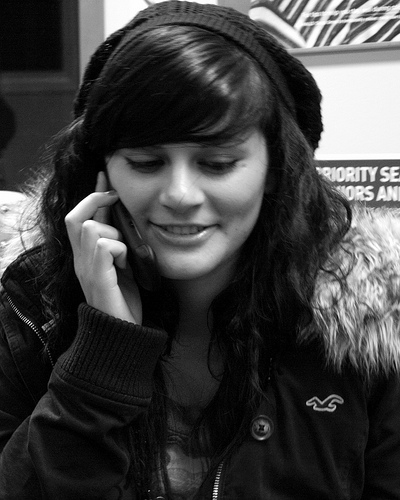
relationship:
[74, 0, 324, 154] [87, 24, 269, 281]
cap on head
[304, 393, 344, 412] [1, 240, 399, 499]
seagull on jacket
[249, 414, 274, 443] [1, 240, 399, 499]
button on jacket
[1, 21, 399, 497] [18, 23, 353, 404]
girl with hair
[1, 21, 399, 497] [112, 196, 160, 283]
girl on phone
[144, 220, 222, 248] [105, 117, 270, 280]
smile on face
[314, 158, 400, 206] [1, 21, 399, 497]
sign behind girl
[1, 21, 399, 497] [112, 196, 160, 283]
girl holding phone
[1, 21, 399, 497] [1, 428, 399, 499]
girl looking down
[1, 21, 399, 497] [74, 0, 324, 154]
girl wearing cap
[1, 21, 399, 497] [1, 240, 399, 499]
girl wearing jacket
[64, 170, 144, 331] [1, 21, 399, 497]
hand of girl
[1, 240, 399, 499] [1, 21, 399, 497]
jacket on girl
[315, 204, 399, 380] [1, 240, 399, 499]
fur on jacket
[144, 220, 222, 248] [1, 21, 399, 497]
smile of girl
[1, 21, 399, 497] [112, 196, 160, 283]
girl using phone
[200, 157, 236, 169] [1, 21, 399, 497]
eye of girl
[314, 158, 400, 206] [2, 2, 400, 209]
sign on wall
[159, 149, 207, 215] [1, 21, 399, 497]
nose of girl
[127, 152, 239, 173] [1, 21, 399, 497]
eyes of girl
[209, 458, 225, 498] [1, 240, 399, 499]
zipper on jacket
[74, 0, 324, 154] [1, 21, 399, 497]
cap on girl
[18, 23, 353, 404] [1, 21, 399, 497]
hair on girl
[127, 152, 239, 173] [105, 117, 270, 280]
eyes on face